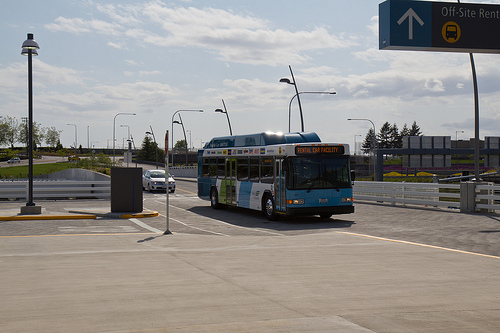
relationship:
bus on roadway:
[195, 132, 355, 217] [0, 179, 500, 255]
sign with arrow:
[378, 0, 500, 56] [395, 6, 425, 41]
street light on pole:
[19, 32, 40, 58] [26, 54, 35, 206]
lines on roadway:
[127, 218, 163, 234] [0, 179, 500, 255]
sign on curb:
[161, 129, 175, 239] [1, 232, 348, 239]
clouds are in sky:
[43, 1, 355, 69] [1, 0, 499, 147]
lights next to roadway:
[64, 110, 205, 167] [0, 179, 500, 255]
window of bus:
[284, 154, 352, 188] [195, 132, 355, 217]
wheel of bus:
[261, 193, 277, 221] [195, 132, 355, 217]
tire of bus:
[208, 186, 220, 209] [195, 132, 355, 217]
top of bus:
[202, 131, 322, 147] [195, 132, 355, 217]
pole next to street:
[26, 54, 35, 206] [0, 179, 500, 255]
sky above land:
[1, 0, 499, 147] [1, 148, 498, 332]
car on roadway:
[143, 169, 176, 191] [0, 179, 500, 255]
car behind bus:
[143, 169, 176, 191] [195, 132, 355, 217]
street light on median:
[19, 32, 40, 58] [1, 207, 159, 220]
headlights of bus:
[288, 198, 354, 206] [195, 132, 355, 217]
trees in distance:
[362, 121, 424, 160] [0, 86, 497, 150]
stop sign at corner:
[161, 129, 175, 239] [160, 228, 359, 256]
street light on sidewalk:
[19, 32, 40, 58] [1, 210, 161, 220]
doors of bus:
[275, 158, 289, 215] [195, 132, 355, 217]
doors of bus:
[224, 157, 238, 208] [195, 132, 355, 217]